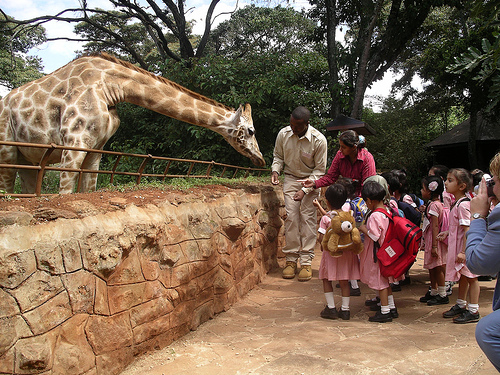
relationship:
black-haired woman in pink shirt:
[296, 130, 377, 200] [313, 148, 377, 190]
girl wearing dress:
[317, 181, 363, 321] [317, 208, 360, 282]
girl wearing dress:
[358, 180, 422, 322] [360, 202, 398, 289]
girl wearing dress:
[420, 176, 448, 306] [423, 199, 445, 269]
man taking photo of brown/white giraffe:
[465, 152, 498, 372] [0, 50, 266, 198]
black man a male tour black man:
[271, 106, 327, 280] [271, 106, 327, 280]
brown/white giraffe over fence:
[0, 50, 266, 198] [0, 139, 273, 205]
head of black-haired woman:
[337, 130, 361, 148] [296, 130, 377, 200]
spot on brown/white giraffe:
[80, 89, 98, 114] [0, 50, 266, 198]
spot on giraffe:
[57, 168, 67, 178] [3, 37, 273, 216]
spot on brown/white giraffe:
[26, 127, 50, 141] [0, 50, 266, 198]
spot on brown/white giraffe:
[229, 114, 238, 122] [0, 50, 266, 198]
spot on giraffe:
[74, 113, 78, 130] [3, 37, 273, 216]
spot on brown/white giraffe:
[215, 107, 225, 117] [0, 50, 266, 198]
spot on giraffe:
[7, 94, 21, 106] [5, 49, 265, 219]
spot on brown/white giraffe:
[80, 67, 98, 79] [0, 50, 266, 198]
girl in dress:
[317, 183, 361, 320] [315, 209, 350, 285]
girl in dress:
[358, 180, 422, 322] [355, 211, 398, 288]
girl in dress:
[419, 176, 450, 306] [421, 200, 448, 270]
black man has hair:
[271, 106, 327, 280] [287, 106, 312, 125]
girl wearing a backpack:
[317, 183, 361, 320] [325, 210, 364, 258]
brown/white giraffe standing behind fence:
[0, 50, 266, 198] [0, 139, 273, 205]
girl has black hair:
[317, 181, 363, 321] [325, 179, 350, 211]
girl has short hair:
[354, 179, 408, 322] [360, 179, 389, 205]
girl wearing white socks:
[317, 181, 363, 321] [321, 292, 353, 312]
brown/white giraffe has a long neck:
[0, 50, 266, 198] [104, 56, 230, 141]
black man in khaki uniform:
[268, 104, 330, 281] [270, 128, 330, 264]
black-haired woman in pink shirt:
[290, 130, 380, 196] [314, 152, 374, 182]